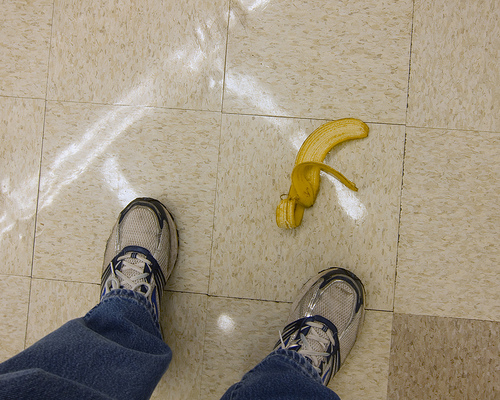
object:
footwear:
[82, 196, 378, 388]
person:
[0, 195, 367, 398]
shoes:
[97, 197, 366, 387]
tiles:
[397, 317, 499, 400]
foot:
[274, 267, 376, 380]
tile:
[383, 312, 498, 392]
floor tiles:
[227, 112, 404, 313]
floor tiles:
[223, 3, 405, 128]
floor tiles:
[405, 124, 498, 311]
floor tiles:
[48, 0, 225, 115]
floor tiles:
[31, 101, 221, 281]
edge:
[395, 115, 402, 320]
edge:
[401, 4, 418, 134]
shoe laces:
[102, 253, 332, 375]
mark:
[304, 186, 311, 206]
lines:
[390, 0, 411, 315]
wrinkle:
[84, 309, 172, 362]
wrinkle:
[0, 367, 117, 398]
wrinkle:
[227, 372, 250, 389]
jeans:
[0, 286, 339, 398]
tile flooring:
[2, 1, 494, 395]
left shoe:
[99, 195, 181, 338]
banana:
[247, 112, 387, 241]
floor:
[0, 3, 494, 400]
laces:
[294, 315, 340, 372]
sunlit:
[27, 33, 287, 188]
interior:
[305, 127, 335, 160]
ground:
[204, 61, 497, 274]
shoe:
[267, 268, 365, 385]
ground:
[25, 38, 495, 313]